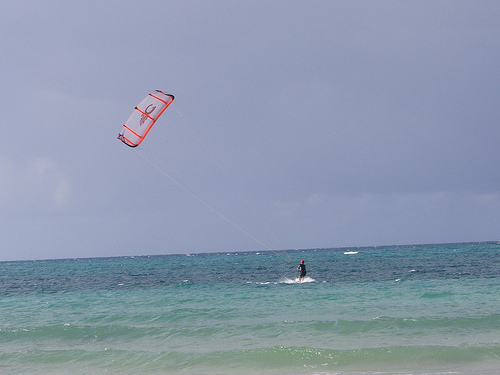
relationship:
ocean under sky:
[16, 260, 486, 374] [12, 17, 488, 207]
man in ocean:
[292, 257, 310, 284] [16, 260, 486, 374]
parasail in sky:
[117, 83, 175, 151] [12, 17, 488, 207]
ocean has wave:
[16, 260, 486, 374] [325, 315, 480, 334]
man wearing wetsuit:
[292, 257, 310, 284] [302, 267, 306, 277]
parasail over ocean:
[117, 83, 175, 151] [16, 260, 486, 374]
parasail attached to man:
[117, 83, 175, 151] [292, 257, 310, 284]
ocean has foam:
[16, 260, 486, 374] [282, 276, 300, 284]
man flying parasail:
[292, 257, 310, 284] [117, 83, 175, 151]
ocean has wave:
[16, 260, 486, 374] [64, 284, 125, 290]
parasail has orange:
[117, 83, 175, 151] [146, 114, 152, 117]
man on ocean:
[292, 257, 310, 284] [16, 260, 486, 374]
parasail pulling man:
[117, 83, 175, 151] [292, 257, 310, 284]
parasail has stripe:
[117, 83, 175, 151] [124, 125, 137, 135]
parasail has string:
[117, 83, 175, 151] [274, 247, 292, 262]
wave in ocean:
[325, 315, 480, 334] [16, 260, 486, 374]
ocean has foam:
[16, 260, 486, 374] [344, 249, 359, 257]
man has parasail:
[292, 257, 310, 284] [117, 83, 175, 151]